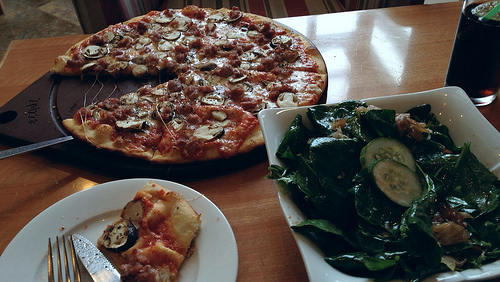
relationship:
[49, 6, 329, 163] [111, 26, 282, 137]
pizza has mushrooms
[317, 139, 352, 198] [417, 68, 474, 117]
spinach in bowl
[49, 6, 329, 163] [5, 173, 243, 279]
pizza on plate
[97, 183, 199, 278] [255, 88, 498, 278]
pizza on plate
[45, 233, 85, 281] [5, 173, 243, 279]
fork on plate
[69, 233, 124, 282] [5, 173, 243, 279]
knife on plate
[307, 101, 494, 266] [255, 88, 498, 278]
salad on plate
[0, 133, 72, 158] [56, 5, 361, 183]
utensil underneath pizza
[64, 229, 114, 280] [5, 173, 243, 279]
knife on plate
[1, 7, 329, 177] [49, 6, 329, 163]
plate for pizza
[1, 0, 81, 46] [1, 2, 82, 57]
tiles on floor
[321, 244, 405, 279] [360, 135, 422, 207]
salad with cucumber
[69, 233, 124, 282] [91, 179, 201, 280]
knife lying on top of pizza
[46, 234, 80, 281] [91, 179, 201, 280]
fork lying on top of pizza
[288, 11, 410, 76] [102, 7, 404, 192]
table with food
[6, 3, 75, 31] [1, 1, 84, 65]
tile covering floor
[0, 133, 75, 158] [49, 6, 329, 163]
utensil for serving pizza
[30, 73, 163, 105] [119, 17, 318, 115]
pan for pizza